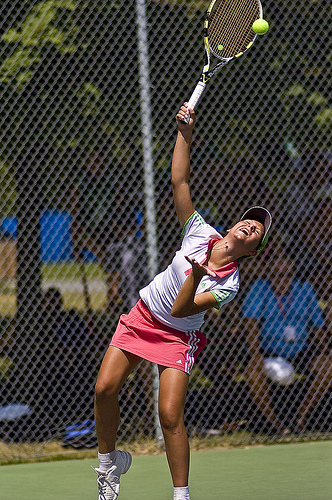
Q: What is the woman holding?
A: Tennis racket.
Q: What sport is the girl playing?
A: Tennis.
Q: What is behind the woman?
A: Fence.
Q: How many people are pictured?
A: At least 2.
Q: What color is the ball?
A: Green.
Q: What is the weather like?
A: Sunny.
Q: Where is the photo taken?
A: At a tennis court.